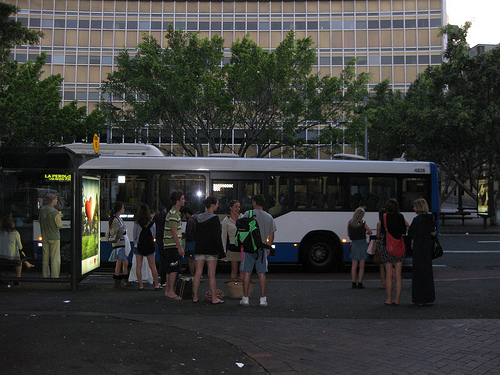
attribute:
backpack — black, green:
[232, 210, 267, 257]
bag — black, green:
[235, 213, 260, 253]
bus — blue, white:
[80, 154, 438, 274]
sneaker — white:
[257, 297, 270, 310]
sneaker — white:
[242, 296, 254, 306]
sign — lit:
[69, 172, 101, 287]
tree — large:
[97, 20, 399, 155]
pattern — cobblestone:
[229, 319, 497, 367]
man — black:
[231, 204, 291, 314]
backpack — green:
[229, 221, 266, 251]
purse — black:
[399, 241, 447, 267]